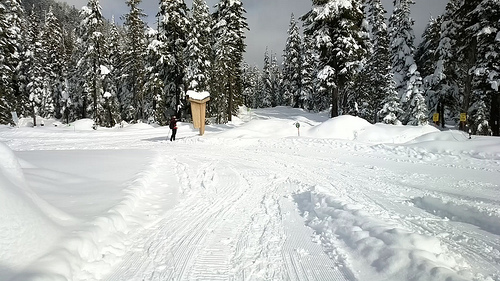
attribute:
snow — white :
[2, 104, 497, 279]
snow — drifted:
[8, 142, 178, 268]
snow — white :
[176, 204, 204, 226]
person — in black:
[160, 100, 207, 162]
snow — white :
[112, 126, 378, 249]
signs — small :
[421, 86, 483, 128]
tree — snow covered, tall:
[376, 0, 430, 125]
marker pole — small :
[294, 120, 301, 137]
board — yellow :
[459, 112, 467, 122]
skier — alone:
[165, 114, 178, 141]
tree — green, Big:
[380, 8, 460, 140]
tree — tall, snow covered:
[414, 1, 499, 135]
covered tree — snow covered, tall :
[45, 29, 166, 90]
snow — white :
[6, 145, 149, 275]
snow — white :
[305, 192, 447, 275]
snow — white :
[305, 117, 497, 178]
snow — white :
[308, 183, 474, 279]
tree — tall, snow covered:
[296, 0, 371, 117]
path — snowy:
[101, 144, 495, 279]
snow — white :
[251, 146, 317, 199]